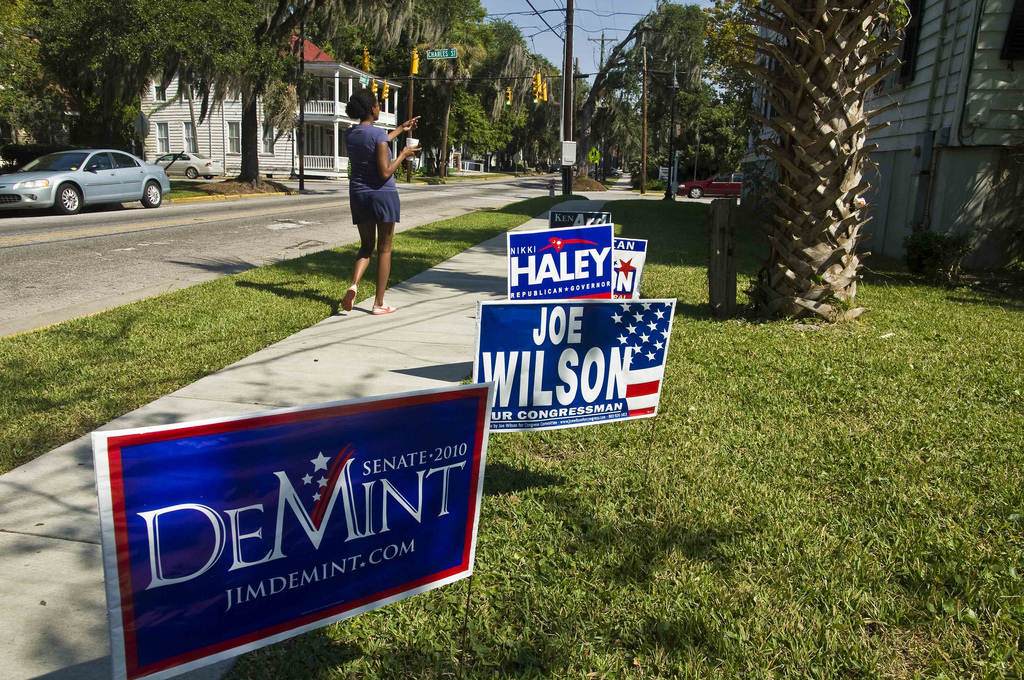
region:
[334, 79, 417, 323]
A woman walking on the sidewalk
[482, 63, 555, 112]
Stoplights over a street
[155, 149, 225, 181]
A parked white car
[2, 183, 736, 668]
A sidewalk next to a street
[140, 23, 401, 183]
A white house next to a street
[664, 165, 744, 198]
A red car on the street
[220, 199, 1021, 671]
Green grass in a yard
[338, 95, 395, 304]
a person walking on the sidewalk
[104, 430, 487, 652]
a sign in the lawn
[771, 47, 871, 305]
the trunk of a tree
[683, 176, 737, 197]
a red car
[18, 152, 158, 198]
a light blue car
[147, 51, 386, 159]
a white house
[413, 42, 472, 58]
a street sign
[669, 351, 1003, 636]
lawn next to the signs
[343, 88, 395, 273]
a lady wearing blue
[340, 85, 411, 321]
Woman walking on sidewalk.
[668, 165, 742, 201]
Red car driving on street.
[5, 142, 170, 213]
Blue car parked on street.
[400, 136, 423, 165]
White Styrofoam cup.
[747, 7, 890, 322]
Brown palm tree on grass.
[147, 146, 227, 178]
White car on street.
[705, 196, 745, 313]
Brown wooden post in grass.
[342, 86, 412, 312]
Woman holding a white cup.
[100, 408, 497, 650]
Blue Senate 2010 sign in grass.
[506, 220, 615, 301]
Red white and blue HALEY sign.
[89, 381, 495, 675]
Blue, red and white DeMint sign.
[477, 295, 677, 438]
Red white and blue Joe Wilson sign.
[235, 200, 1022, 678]
A green grass area with a lot of signs.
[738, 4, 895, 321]
Large palm tree trunk.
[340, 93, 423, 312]
Dark woman walking in a blue skirt.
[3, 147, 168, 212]
A blue parked car.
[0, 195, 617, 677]
Long grey sidewalk a woman is walking on.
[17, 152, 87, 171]
Front windshield on a blue car.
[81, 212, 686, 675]
four political campaigning signs stuck in ground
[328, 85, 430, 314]
woman walking down sidewalk in town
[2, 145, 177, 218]
blue sedan parked beside curb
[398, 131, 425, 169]
drinking cup in woman's right hand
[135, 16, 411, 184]
large two-story home with red roof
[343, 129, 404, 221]
The dark blue clothing the woman is wearing.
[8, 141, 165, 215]
The blue car in the street.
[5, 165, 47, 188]
The right headlight of the blue car in the street.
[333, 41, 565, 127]
The yellow street lights hanging above the street.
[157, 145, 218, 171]
The white car parked in front of the white building.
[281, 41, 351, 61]
The red roof above the white house.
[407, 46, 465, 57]
The green street sign hanging above the street.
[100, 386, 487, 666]
The sign that reads DeMint.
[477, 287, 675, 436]
The sign that reads Joe Wilson.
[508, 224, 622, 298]
The sign that reads Haley.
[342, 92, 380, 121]
the hair of a woman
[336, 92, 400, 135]
the head of a woman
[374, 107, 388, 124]
the face of a woman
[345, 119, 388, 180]
the torso of a woman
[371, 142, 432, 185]
the right arm of a woman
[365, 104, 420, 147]
the left arm of a woman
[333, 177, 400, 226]
the skirt of a woman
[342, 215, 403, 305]
the legs of a woman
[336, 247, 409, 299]
the calves of a woman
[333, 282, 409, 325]
the shoes of a woman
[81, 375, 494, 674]
the sign is blue